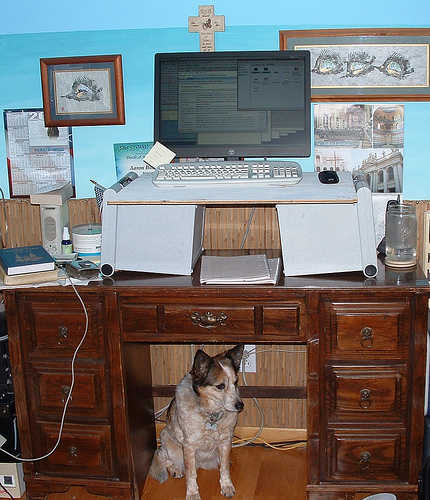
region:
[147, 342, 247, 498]
a dog sitting under a desk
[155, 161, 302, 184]
a white computer keyboard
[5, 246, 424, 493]
a dark wooden desk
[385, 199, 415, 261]
a glass mason jar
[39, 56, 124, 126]
a framed picture on the wall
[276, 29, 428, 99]
a framed picture on the wall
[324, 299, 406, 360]
a drawer in a desk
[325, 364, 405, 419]
a drawer in a desk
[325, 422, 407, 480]
a drawer in a desk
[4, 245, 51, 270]
a book on a desk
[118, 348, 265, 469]
dog under the table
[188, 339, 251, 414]
head of the dog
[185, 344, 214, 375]
ear of the dog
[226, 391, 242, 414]
nose of the dog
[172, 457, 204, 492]
foot of the dog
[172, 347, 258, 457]
dog sitting under table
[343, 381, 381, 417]
handle on the drawer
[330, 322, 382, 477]
three handles on the drawer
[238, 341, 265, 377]
plug in the background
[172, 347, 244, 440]
light and dark dog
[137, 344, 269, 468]
dog under the desk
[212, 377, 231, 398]
eye of the dog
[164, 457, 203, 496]
leg of the dog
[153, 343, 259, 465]
dog sitting down on the floor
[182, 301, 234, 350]
handle on the drawer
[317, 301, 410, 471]
three different drawers on the table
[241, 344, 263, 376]
outlet on the wall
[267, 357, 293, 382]
brown wall next to dog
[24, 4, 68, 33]
wall behind the computer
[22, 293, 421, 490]
the table is wooden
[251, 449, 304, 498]
the floor is wooden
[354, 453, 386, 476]
the handle is circular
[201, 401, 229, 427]
the tag is on the neck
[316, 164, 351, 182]
the phone is black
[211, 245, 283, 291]
twoo books are on the surface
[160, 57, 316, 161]
the monitor is on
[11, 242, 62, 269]
the book is blue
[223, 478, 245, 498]
claws are on the leg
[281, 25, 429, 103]
picture is on the wall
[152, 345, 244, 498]
brown dog sitting under the desl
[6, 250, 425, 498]
old wooden desk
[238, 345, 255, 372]
electrical outlet under the desk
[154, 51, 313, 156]
computer monitor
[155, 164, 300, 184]
gray computer keyboard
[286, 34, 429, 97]
painting of three fish to the right of the monitor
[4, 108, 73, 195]
poster of a calendar to the left of the desk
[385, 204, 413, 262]
glass jar on the desk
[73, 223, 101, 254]
spindle of black discs on the desk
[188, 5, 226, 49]
cross above the monitor